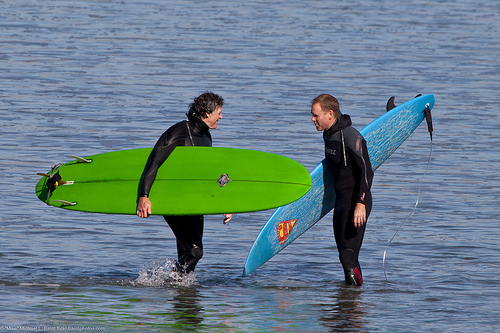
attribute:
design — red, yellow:
[275, 217, 297, 243]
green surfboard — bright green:
[35, 147, 316, 217]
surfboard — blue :
[241, 92, 435, 277]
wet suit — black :
[308, 127, 380, 300]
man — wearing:
[321, 116, 374, 288]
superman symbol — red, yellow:
[273, 213, 300, 248]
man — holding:
[313, 91, 385, 263]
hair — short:
[317, 94, 335, 108]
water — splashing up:
[127, 256, 225, 327]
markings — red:
[352, 130, 367, 159]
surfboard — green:
[33, 144, 313, 229]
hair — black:
[182, 93, 229, 120]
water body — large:
[1, 2, 499, 329]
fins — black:
[412, 107, 442, 136]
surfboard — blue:
[237, 84, 442, 296]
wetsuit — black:
[321, 120, 393, 283]